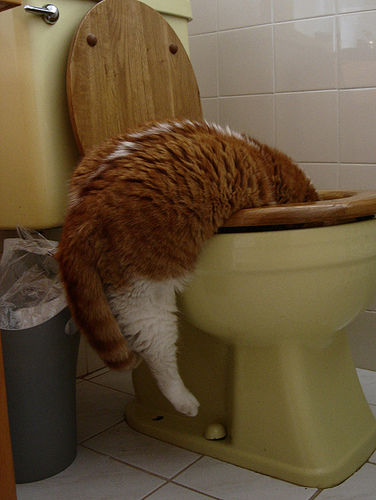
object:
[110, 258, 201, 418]
leg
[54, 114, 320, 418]
cat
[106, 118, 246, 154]
back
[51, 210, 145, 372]
tail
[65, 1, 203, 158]
lid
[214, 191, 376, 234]
seat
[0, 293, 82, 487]
trash can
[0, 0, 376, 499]
bathroom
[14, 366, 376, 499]
floor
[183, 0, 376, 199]
wall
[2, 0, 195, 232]
tank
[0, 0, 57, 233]
side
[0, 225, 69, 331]
bag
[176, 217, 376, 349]
bowl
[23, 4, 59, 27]
handle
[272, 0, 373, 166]
tiles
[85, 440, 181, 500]
tiles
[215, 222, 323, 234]
stopper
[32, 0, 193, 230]
back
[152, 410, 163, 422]
spot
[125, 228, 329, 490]
side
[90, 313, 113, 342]
stripes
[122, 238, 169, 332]
fur